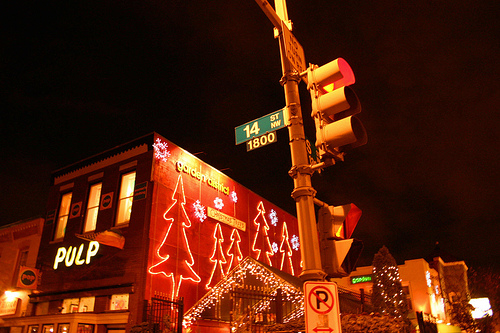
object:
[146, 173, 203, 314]
lights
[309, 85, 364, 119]
light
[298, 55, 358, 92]
light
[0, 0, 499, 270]
sky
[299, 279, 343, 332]
sign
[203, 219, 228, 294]
tree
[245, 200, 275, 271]
tree